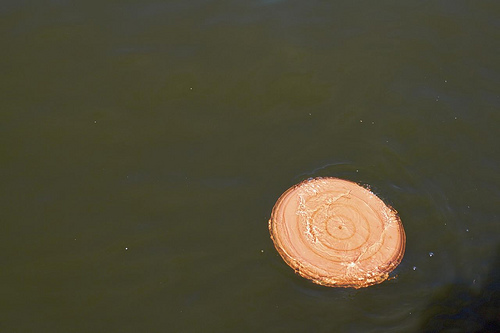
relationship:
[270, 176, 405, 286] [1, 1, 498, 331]
frisbee in water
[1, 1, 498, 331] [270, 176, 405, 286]
water around frisbee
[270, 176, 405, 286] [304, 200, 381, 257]
frisbee has lines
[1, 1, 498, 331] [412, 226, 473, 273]
water has air bubbles